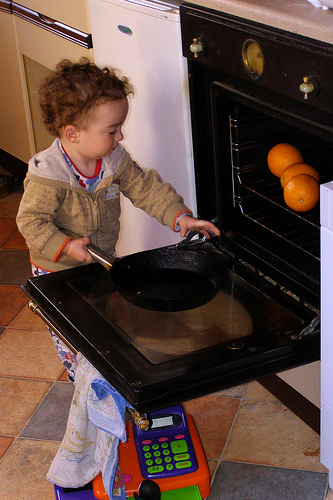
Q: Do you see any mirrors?
A: No, there are no mirrors.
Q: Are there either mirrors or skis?
A: No, there are no mirrors or skis.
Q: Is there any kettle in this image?
A: No, there are no kettles.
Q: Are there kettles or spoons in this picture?
A: No, there are no kettles or spoons.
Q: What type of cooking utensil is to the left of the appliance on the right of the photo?
A: The cooking utensil is a skillet.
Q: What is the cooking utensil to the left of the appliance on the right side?
A: The cooking utensil is a skillet.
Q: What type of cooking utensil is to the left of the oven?
A: The cooking utensil is a skillet.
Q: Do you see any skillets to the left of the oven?
A: Yes, there is a skillet to the left of the oven.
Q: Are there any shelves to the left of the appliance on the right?
A: No, there is a skillet to the left of the oven.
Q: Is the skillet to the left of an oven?
A: Yes, the skillet is to the left of an oven.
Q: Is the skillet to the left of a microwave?
A: No, the skillet is to the left of an oven.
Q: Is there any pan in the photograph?
A: Yes, there is a pan.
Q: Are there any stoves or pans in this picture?
A: Yes, there is a pan.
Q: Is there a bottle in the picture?
A: No, there are no bottles.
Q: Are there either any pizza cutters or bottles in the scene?
A: No, there are no bottles or pizza cutters.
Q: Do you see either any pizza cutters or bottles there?
A: No, there are no bottles or pizza cutters.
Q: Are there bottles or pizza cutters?
A: No, there are no bottles or pizza cutters.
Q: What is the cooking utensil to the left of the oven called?
A: The cooking utensil is a pan.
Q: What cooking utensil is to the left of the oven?
A: The cooking utensil is a pan.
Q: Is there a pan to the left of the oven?
A: Yes, there is a pan to the left of the oven.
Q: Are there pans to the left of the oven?
A: Yes, there is a pan to the left of the oven.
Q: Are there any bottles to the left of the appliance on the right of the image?
A: No, there is a pan to the left of the oven.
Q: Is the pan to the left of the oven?
A: Yes, the pan is to the left of the oven.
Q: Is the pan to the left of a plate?
A: No, the pan is to the left of the oven.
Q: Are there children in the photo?
A: Yes, there is a child.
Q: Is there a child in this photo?
A: Yes, there is a child.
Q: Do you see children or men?
A: Yes, there is a child.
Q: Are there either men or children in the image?
A: Yes, there is a child.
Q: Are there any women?
A: No, there are no women.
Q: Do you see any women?
A: No, there are no women.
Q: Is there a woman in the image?
A: No, there are no women.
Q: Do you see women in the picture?
A: No, there are no women.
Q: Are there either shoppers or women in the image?
A: No, there are no women or shoppers.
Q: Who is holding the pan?
A: The kid is holding the pan.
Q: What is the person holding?
A: The child is holding the pan.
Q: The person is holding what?
A: The child is holding the pan.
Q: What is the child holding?
A: The child is holding the pan.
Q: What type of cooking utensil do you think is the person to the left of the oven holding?
A: The kid is holding the pan.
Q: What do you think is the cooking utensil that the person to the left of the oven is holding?
A: The cooking utensil is a pan.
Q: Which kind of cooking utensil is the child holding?
A: The kid is holding the pan.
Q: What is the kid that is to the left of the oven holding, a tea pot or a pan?
A: The kid is holding a pan.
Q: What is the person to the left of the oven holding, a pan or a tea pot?
A: The kid is holding a pan.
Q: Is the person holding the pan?
A: Yes, the child is holding the pan.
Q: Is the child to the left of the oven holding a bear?
A: No, the child is holding the pan.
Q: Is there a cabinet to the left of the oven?
A: No, there is a child to the left of the oven.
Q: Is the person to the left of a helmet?
A: No, the child is to the left of the oven.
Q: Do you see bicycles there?
A: No, there are no bicycles.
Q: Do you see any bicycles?
A: No, there are no bicycles.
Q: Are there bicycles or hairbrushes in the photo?
A: No, there are no bicycles or hairbrushes.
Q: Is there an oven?
A: Yes, there is an oven.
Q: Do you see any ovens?
A: Yes, there is an oven.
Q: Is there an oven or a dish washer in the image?
A: Yes, there is an oven.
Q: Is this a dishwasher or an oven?
A: This is an oven.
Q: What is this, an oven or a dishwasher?
A: This is an oven.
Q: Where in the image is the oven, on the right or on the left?
A: The oven is on the right of the image.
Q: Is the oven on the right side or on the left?
A: The oven is on the right of the image.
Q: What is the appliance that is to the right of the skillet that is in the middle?
A: The appliance is an oven.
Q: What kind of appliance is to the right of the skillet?
A: The appliance is an oven.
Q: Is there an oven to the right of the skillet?
A: Yes, there is an oven to the right of the skillet.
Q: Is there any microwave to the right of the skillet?
A: No, there is an oven to the right of the skillet.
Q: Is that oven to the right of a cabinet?
A: No, the oven is to the right of a skillet.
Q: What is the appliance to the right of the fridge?
A: The appliance is an oven.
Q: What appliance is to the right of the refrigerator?
A: The appliance is an oven.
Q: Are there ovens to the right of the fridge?
A: Yes, there is an oven to the right of the fridge.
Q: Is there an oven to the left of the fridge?
A: No, the oven is to the right of the fridge.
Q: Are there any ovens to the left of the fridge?
A: No, the oven is to the right of the fridge.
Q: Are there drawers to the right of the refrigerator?
A: No, there is an oven to the right of the refrigerator.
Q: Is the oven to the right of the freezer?
A: Yes, the oven is to the right of the freezer.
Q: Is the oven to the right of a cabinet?
A: No, the oven is to the right of the freezer.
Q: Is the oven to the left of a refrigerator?
A: No, the oven is to the right of a refrigerator.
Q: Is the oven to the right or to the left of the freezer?
A: The oven is to the right of the freezer.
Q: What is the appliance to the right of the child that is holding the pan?
A: The appliance is an oven.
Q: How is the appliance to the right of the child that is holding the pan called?
A: The appliance is an oven.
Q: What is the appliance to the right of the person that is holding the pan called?
A: The appliance is an oven.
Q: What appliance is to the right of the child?
A: The appliance is an oven.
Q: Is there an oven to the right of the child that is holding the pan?
A: Yes, there is an oven to the right of the kid.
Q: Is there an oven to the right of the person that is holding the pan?
A: Yes, there is an oven to the right of the kid.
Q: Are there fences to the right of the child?
A: No, there is an oven to the right of the child.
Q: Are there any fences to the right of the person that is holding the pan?
A: No, there is an oven to the right of the child.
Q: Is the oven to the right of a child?
A: Yes, the oven is to the right of a child.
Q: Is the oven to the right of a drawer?
A: No, the oven is to the right of a child.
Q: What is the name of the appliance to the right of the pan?
A: The appliance is an oven.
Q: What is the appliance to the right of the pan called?
A: The appliance is an oven.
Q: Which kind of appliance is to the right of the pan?
A: The appliance is an oven.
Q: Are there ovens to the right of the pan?
A: Yes, there is an oven to the right of the pan.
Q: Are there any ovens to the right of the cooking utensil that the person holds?
A: Yes, there is an oven to the right of the pan.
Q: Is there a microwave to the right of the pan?
A: No, there is an oven to the right of the pan.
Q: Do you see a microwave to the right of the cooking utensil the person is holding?
A: No, there is an oven to the right of the pan.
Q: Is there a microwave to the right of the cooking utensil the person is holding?
A: No, there is an oven to the right of the pan.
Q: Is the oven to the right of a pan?
A: Yes, the oven is to the right of a pan.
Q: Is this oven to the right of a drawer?
A: No, the oven is to the right of a pan.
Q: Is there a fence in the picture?
A: No, there are no fences.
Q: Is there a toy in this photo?
A: Yes, there is a toy.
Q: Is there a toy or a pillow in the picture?
A: Yes, there is a toy.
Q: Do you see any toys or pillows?
A: Yes, there is a toy.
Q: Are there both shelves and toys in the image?
A: No, there is a toy but no shelves.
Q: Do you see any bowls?
A: No, there are no bowls.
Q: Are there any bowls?
A: No, there are no bowls.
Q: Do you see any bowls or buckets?
A: No, there are no bowls or buckets.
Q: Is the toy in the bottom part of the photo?
A: Yes, the toy is in the bottom of the image.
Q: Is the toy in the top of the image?
A: No, the toy is in the bottom of the image.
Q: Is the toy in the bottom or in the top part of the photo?
A: The toy is in the bottom of the image.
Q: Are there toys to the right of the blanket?
A: Yes, there is a toy to the right of the blanket.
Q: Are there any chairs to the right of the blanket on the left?
A: No, there is a toy to the right of the blanket.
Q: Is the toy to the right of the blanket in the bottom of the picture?
A: Yes, the toy is to the right of the blanket.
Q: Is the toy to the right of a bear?
A: No, the toy is to the right of the blanket.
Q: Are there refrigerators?
A: Yes, there is a refrigerator.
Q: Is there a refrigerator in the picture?
A: Yes, there is a refrigerator.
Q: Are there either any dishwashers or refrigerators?
A: Yes, there is a refrigerator.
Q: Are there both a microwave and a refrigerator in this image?
A: No, there is a refrigerator but no microwaves.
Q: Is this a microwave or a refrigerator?
A: This is a refrigerator.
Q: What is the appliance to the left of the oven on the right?
A: The appliance is a refrigerator.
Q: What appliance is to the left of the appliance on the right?
A: The appliance is a refrigerator.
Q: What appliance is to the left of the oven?
A: The appliance is a refrigerator.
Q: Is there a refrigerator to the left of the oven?
A: Yes, there is a refrigerator to the left of the oven.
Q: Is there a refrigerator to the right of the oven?
A: No, the refrigerator is to the left of the oven.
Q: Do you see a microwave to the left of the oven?
A: No, there is a refrigerator to the left of the oven.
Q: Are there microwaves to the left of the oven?
A: No, there is a refrigerator to the left of the oven.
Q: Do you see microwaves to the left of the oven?
A: No, there is a refrigerator to the left of the oven.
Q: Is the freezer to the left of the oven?
A: Yes, the freezer is to the left of the oven.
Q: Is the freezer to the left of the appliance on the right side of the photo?
A: Yes, the freezer is to the left of the oven.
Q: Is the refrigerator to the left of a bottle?
A: No, the refrigerator is to the left of the oven.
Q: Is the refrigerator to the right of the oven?
A: No, the refrigerator is to the left of the oven.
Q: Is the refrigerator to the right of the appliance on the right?
A: No, the refrigerator is to the left of the oven.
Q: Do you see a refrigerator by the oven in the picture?
A: Yes, there is a refrigerator by the oven.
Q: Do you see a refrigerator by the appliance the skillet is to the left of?
A: Yes, there is a refrigerator by the oven.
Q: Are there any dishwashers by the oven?
A: No, there is a refrigerator by the oven.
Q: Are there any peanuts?
A: No, there are no peanuts.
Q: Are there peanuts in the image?
A: No, there are no peanuts.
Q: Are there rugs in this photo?
A: No, there are no rugs.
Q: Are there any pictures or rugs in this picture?
A: No, there are no rugs or pictures.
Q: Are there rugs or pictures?
A: No, there are no rugs or pictures.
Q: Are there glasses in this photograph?
A: No, there are no glasses.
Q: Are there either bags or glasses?
A: No, there are no glasses or bags.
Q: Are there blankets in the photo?
A: Yes, there is a blanket.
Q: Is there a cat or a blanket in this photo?
A: Yes, there is a blanket.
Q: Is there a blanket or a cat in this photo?
A: Yes, there is a blanket.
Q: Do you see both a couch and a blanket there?
A: No, there is a blanket but no couches.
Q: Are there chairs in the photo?
A: No, there are no chairs.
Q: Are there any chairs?
A: No, there are no chairs.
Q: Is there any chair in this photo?
A: No, there are no chairs.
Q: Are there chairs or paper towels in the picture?
A: No, there are no chairs or paper towels.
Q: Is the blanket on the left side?
A: Yes, the blanket is on the left of the image.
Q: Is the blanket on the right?
A: No, the blanket is on the left of the image.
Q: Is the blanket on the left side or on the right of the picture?
A: The blanket is on the left of the image.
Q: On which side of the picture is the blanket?
A: The blanket is on the left of the image.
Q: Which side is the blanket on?
A: The blanket is on the left of the image.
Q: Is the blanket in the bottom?
A: Yes, the blanket is in the bottom of the image.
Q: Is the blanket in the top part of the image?
A: No, the blanket is in the bottom of the image.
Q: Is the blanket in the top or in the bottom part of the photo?
A: The blanket is in the bottom of the image.